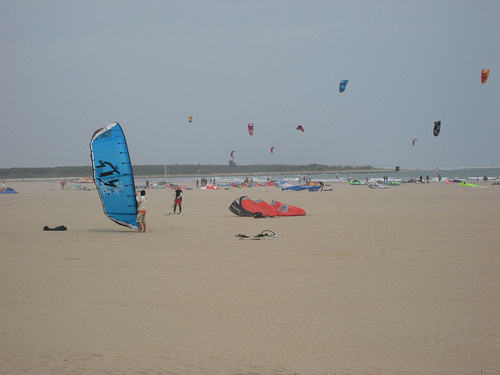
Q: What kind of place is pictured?
A: It is a beach.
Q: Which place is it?
A: It is a beach.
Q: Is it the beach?
A: Yes, it is the beach.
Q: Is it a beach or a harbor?
A: It is a beach.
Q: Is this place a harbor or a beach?
A: It is a beach.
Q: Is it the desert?
A: No, it is the beach.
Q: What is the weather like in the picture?
A: It is clear.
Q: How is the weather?
A: It is clear.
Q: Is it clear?
A: Yes, it is clear.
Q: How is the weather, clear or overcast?
A: It is clear.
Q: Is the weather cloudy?
A: No, it is clear.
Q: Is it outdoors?
A: Yes, it is outdoors.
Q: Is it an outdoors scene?
A: Yes, it is outdoors.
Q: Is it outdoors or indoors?
A: It is outdoors.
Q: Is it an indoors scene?
A: No, it is outdoors.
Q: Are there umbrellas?
A: No, there are no umbrellas.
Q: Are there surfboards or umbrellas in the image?
A: No, there are no umbrellas or surfboards.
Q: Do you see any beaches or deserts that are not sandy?
A: No, there is a beach but it is sandy.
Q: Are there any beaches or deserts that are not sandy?
A: No, there is a beach but it is sandy.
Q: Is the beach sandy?
A: Yes, the beach is sandy.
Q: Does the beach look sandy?
A: Yes, the beach is sandy.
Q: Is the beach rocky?
A: No, the beach is sandy.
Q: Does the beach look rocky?
A: No, the beach is sandy.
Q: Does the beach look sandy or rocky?
A: The beach is sandy.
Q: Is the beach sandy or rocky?
A: The beach is sandy.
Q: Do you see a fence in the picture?
A: No, there are no fences.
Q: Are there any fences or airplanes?
A: No, there are no fences or airplanes.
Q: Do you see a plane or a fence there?
A: No, there are no fences or airplanes.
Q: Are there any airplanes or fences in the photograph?
A: No, there are no fences or airplanes.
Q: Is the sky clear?
A: Yes, the sky is clear.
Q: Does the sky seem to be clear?
A: Yes, the sky is clear.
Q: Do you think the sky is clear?
A: Yes, the sky is clear.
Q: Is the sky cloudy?
A: No, the sky is clear.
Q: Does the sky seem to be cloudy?
A: No, the sky is clear.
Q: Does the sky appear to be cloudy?
A: No, the sky is clear.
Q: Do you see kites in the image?
A: Yes, there is a kite.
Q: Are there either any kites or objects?
A: Yes, there is a kite.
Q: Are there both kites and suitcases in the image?
A: No, there is a kite but no suitcases.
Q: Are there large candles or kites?
A: Yes, there is a large kite.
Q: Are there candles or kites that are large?
A: Yes, the kite is large.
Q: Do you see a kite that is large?
A: Yes, there is a large kite.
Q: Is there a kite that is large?
A: Yes, there is a large kite.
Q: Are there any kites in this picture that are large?
A: Yes, there is a kite that is large.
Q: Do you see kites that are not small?
A: Yes, there is a large kite.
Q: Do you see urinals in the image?
A: No, there are no urinals.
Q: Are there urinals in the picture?
A: No, there are no urinals.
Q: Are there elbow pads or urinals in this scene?
A: No, there are no urinals or elbow pads.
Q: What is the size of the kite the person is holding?
A: The kite is large.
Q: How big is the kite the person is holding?
A: The kite is large.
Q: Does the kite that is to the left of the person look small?
A: No, the kite is large.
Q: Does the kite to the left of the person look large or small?
A: The kite is large.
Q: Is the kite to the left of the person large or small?
A: The kite is large.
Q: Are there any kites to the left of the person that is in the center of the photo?
A: Yes, there is a kite to the left of the person.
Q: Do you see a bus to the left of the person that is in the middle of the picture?
A: No, there is a kite to the left of the person.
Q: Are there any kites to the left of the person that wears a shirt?
A: Yes, there is a kite to the left of the person.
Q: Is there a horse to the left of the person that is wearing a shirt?
A: No, there is a kite to the left of the person.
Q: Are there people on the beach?
A: Yes, there is a person on the beach.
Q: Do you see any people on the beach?
A: Yes, there is a person on the beach.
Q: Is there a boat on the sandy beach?
A: No, there is a person on the beach.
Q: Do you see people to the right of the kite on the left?
A: Yes, there is a person to the right of the kite.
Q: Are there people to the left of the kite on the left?
A: No, the person is to the right of the kite.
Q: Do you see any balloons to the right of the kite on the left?
A: No, there is a person to the right of the kite.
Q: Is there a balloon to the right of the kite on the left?
A: No, there is a person to the right of the kite.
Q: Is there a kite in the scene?
A: Yes, there is a kite.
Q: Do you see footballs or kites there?
A: Yes, there is a kite.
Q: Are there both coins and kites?
A: No, there is a kite but no coins.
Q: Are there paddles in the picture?
A: No, there are no paddles.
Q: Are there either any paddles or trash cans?
A: No, there are no paddles or trash cans.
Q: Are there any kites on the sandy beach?
A: Yes, there is a kite on the beach.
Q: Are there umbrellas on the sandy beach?
A: No, there is a kite on the beach.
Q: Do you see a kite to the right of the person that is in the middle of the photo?
A: Yes, there is a kite to the right of the person.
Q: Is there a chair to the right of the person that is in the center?
A: No, there is a kite to the right of the person.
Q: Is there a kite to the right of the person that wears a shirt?
A: Yes, there is a kite to the right of the person.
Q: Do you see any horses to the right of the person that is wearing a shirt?
A: No, there is a kite to the right of the person.